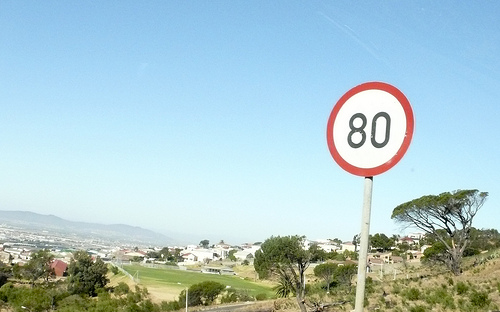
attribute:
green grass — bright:
[147, 263, 188, 288]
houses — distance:
[2, 225, 425, 277]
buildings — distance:
[0, 221, 433, 278]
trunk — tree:
[261, 250, 323, 302]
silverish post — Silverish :
[357, 181, 369, 310]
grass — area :
[117, 257, 290, 299]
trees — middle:
[218, 195, 329, 309]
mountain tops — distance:
[11, 155, 158, 232]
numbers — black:
[345, 103, 397, 154]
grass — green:
[128, 262, 278, 294]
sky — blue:
[1, 0, 498, 256]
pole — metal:
[326, 172, 396, 289]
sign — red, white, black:
[285, 53, 415, 180]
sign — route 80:
[299, 64, 456, 197]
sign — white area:
[321, 79, 418, 179]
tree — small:
[250, 230, 325, 303]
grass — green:
[116, 260, 273, 300]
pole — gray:
[347, 174, 378, 310]